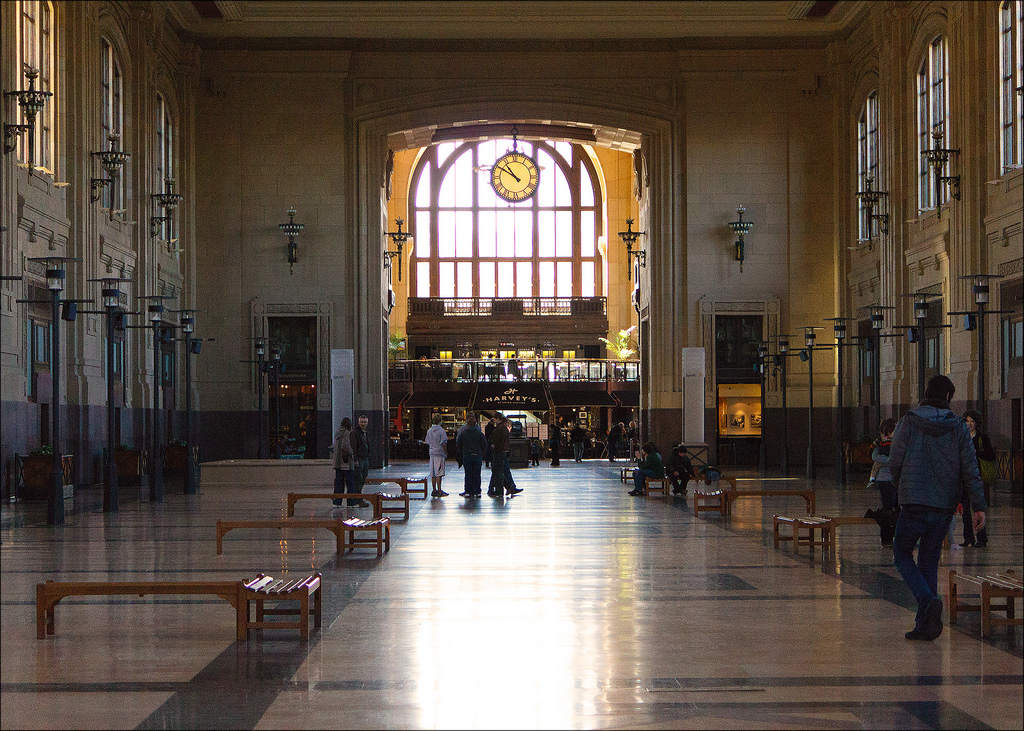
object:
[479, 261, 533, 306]
window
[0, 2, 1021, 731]
building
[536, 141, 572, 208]
window